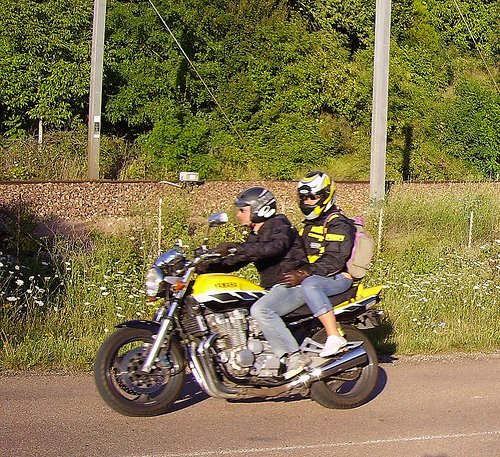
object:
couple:
[206, 172, 369, 383]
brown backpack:
[348, 217, 372, 279]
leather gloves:
[278, 269, 305, 288]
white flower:
[16, 280, 24, 286]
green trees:
[1, 0, 495, 181]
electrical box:
[179, 171, 200, 182]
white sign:
[92, 116, 101, 138]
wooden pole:
[89, 0, 105, 180]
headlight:
[143, 266, 162, 297]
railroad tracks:
[4, 177, 479, 194]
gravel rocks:
[16, 176, 157, 223]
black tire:
[93, 323, 185, 416]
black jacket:
[198, 214, 308, 287]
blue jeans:
[300, 272, 347, 320]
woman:
[299, 171, 376, 378]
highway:
[0, 369, 499, 455]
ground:
[0, 180, 498, 455]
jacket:
[298, 214, 355, 276]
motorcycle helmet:
[297, 171, 336, 220]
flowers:
[7, 212, 498, 346]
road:
[3, 352, 480, 453]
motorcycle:
[89, 169, 385, 419]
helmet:
[297, 170, 336, 221]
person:
[211, 186, 316, 380]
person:
[280, 169, 356, 357]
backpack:
[323, 212, 375, 278]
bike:
[94, 209, 386, 409]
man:
[189, 187, 310, 380]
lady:
[288, 170, 353, 359]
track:
[1, 177, 484, 186]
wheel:
[93, 318, 188, 417]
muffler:
[185, 330, 366, 396]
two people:
[225, 172, 365, 385]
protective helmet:
[234, 186, 278, 222]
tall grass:
[23, 243, 100, 371]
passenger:
[279, 171, 356, 357]